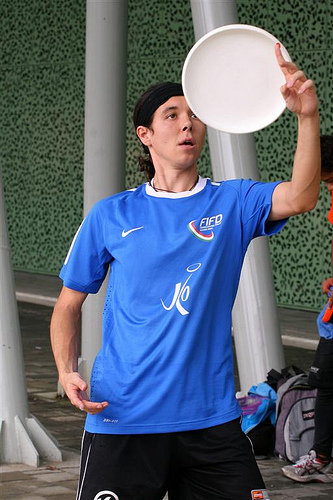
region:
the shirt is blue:
[42, 204, 267, 497]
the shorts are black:
[52, 398, 236, 497]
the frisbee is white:
[175, 30, 285, 160]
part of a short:
[222, 449, 248, 489]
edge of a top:
[151, 406, 187, 446]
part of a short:
[148, 467, 172, 497]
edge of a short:
[160, 428, 187, 475]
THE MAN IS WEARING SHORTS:
[62, 419, 270, 499]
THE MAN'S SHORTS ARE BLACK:
[63, 414, 278, 498]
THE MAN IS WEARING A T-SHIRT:
[45, 169, 300, 444]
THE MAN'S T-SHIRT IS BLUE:
[47, 166, 291, 435]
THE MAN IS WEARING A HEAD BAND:
[129, 76, 193, 134]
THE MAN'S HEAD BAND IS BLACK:
[122, 71, 193, 139]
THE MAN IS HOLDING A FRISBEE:
[174, 18, 322, 153]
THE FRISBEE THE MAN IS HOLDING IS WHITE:
[170, 14, 302, 154]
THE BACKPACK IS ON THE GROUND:
[269, 368, 332, 474]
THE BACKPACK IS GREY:
[272, 373, 332, 463]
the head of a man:
[122, 78, 211, 176]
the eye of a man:
[162, 109, 179, 124]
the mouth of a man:
[173, 135, 200, 151]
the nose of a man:
[179, 109, 194, 134]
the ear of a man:
[134, 121, 153, 147]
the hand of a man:
[54, 366, 111, 421]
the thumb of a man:
[67, 368, 91, 393]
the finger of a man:
[67, 386, 87, 412]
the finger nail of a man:
[94, 403, 103, 410]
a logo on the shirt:
[118, 218, 148, 242]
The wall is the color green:
[12, 25, 72, 237]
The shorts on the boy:
[72, 417, 272, 498]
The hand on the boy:
[58, 367, 112, 417]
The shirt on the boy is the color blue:
[57, 172, 292, 438]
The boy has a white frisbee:
[173, 17, 320, 224]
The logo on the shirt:
[187, 211, 226, 241]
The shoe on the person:
[278, 447, 332, 486]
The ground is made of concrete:
[5, 466, 79, 498]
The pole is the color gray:
[78, 5, 131, 196]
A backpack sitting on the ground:
[267, 371, 323, 468]